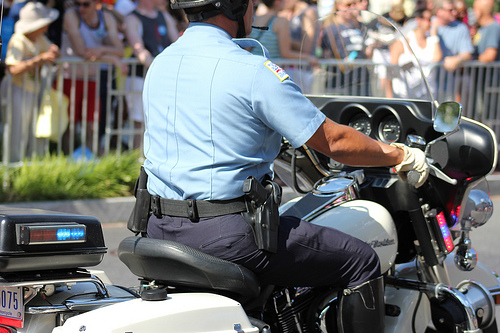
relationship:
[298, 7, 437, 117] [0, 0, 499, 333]
visor on bike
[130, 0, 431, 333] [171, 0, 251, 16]
an officer has cap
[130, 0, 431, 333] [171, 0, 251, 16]
an officer wearing cap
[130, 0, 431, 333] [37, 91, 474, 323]
an officer on motorcycle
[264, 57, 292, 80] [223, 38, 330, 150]
patch on sleeve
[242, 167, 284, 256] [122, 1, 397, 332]
gun on cop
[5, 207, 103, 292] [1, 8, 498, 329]
light on motorcycle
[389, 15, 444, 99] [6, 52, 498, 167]
person is behind gate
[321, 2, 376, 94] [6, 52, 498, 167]
person is behind gate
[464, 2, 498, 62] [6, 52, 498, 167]
person is behind gate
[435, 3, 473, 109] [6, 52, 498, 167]
person is behind gate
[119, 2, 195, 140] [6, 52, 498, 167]
person is behind gate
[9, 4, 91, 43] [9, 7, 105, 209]
hat is on person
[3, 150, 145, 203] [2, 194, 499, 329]
grass is by street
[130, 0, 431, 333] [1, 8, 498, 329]
an officer is on motorcycle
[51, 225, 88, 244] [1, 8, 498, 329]
blue light is on motorcycle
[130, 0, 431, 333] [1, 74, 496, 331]
an officer is on bike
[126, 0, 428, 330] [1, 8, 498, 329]
cap is on motorcycle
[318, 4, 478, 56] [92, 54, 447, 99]
people is behind fence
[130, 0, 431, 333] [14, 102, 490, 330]
an officer is on motorcycle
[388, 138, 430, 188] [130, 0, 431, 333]
glove is on an officer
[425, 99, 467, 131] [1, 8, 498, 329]
mirror is on motorcycle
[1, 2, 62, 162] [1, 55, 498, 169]
people is behind fence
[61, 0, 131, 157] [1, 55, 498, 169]
person is behind fence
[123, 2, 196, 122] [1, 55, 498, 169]
person is behind fence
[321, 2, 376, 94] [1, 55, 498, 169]
person is behind fence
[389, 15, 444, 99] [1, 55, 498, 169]
person is behind fence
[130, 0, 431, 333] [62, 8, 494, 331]
an officer sitting on bike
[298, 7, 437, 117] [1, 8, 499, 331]
visor on bike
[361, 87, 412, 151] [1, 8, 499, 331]
odometer on bike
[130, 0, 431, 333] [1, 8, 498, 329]
an officer riding motorcycle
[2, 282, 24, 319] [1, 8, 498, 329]
license plate on motorcycle